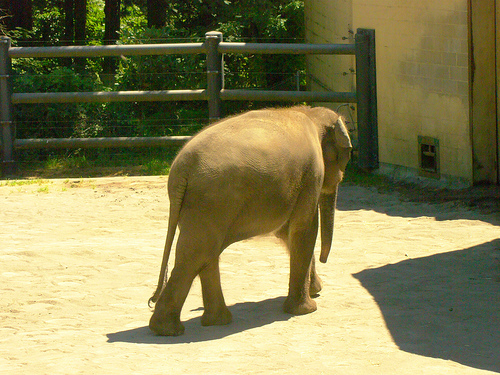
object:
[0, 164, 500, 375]
ground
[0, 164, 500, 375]
dirt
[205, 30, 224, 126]
post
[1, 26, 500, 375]
enclosoure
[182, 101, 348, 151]
hairs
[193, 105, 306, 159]
back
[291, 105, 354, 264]
head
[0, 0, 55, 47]
trees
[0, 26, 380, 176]
fence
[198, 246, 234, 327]
leg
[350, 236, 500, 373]
shadow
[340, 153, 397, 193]
grass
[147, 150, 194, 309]
tail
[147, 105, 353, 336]
elephant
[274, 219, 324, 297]
leg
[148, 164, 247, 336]
leg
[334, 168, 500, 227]
shadows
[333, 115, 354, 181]
ear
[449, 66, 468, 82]
bricks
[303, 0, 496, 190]
wall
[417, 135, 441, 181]
window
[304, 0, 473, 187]
brick wall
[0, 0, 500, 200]
background